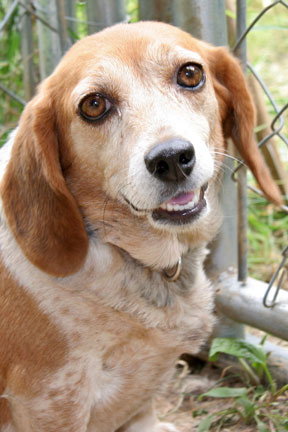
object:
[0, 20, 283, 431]
dog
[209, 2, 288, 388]
fence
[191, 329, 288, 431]
plant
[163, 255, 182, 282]
ring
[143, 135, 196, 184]
nose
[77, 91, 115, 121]
eye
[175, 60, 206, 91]
eye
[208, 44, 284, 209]
ear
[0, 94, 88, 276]
ear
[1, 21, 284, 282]
head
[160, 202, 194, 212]
teeth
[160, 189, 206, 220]
mouth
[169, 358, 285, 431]
ground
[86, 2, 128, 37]
post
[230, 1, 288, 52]
link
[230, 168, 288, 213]
link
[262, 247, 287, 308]
link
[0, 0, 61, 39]
link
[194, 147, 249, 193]
whisker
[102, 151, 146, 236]
whisker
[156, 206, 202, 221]
lip